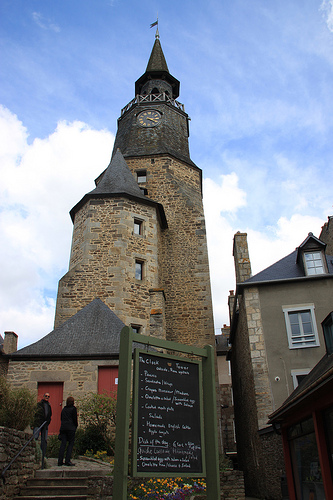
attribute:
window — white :
[302, 246, 330, 274]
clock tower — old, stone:
[5, 18, 223, 456]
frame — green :
[132, 347, 205, 481]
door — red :
[35, 376, 83, 435]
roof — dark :
[144, 38, 172, 70]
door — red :
[31, 379, 76, 450]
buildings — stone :
[29, 154, 222, 348]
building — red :
[270, 312, 330, 499]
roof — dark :
[273, 345, 331, 415]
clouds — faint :
[9, 115, 85, 181]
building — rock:
[2, 14, 222, 495]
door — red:
[96, 363, 118, 408]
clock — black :
[137, 110, 162, 126]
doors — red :
[34, 364, 118, 436]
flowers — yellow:
[127, 474, 203, 498]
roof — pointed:
[11, 294, 159, 362]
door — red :
[34, 380, 64, 435]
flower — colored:
[158, 480, 165, 486]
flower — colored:
[182, 485, 187, 490]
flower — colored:
[138, 482, 144, 487]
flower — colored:
[174, 477, 180, 482]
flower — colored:
[156, 490, 162, 495]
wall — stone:
[0, 429, 35, 496]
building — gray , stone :
[224, 223, 332, 497]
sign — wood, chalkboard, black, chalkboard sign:
[130, 346, 208, 478]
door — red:
[36, 382, 63, 438]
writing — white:
[141, 363, 196, 467]